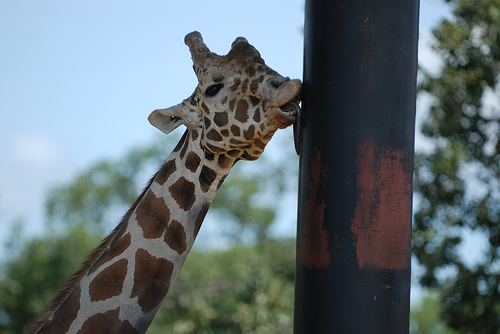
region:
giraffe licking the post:
[157, 23, 374, 240]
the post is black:
[295, 14, 424, 331]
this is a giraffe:
[17, 24, 450, 301]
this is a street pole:
[295, 38, 433, 310]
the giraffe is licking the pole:
[66, 49, 268, 297]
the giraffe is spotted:
[22, 172, 121, 319]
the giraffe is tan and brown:
[82, 207, 222, 317]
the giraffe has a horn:
[162, 35, 266, 67]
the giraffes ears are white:
[140, 65, 212, 158]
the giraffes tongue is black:
[272, 113, 337, 166]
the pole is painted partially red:
[277, 121, 442, 296]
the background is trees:
[31, 22, 472, 282]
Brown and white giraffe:
[22, 28, 317, 332]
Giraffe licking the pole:
[43, 23, 333, 327]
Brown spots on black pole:
[282, 130, 442, 311]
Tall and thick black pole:
[291, 1, 457, 331]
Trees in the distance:
[5, 132, 397, 332]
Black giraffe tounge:
[280, 96, 317, 166]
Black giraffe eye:
[189, 77, 239, 107]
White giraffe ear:
[133, 80, 194, 145]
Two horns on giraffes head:
[184, 15, 272, 89]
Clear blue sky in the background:
[5, 2, 497, 269]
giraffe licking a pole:
[147, 12, 323, 197]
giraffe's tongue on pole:
[166, 13, 353, 163]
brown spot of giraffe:
[165, 172, 201, 227]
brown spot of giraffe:
[164, 210, 198, 267]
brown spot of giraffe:
[134, 183, 171, 246]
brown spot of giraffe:
[129, 249, 181, 329]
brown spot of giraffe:
[79, 264, 139, 301]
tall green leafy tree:
[430, 9, 498, 309]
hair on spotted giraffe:
[19, 278, 85, 300]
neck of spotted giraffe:
[47, 160, 269, 320]